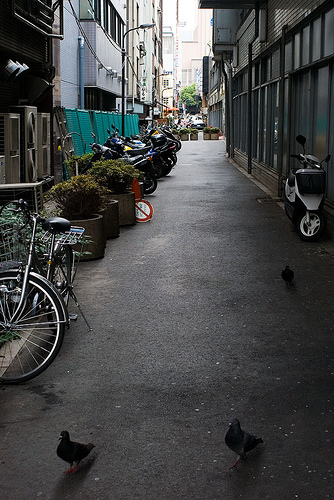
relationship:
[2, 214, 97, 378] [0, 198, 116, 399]
parked bicycle wire basket parket bicycle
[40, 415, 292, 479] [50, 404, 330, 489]
two pigeons walking on ground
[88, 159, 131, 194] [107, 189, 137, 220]
shrub in wood planter